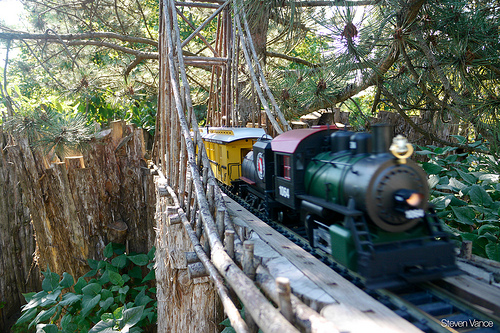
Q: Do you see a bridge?
A: Yes, there is a bridge.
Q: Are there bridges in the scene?
A: Yes, there is a bridge.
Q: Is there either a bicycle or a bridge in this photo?
A: Yes, there is a bridge.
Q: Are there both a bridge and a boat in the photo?
A: No, there is a bridge but no boats.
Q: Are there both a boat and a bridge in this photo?
A: No, there is a bridge but no boats.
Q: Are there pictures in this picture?
A: No, there are no pictures.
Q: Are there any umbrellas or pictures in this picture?
A: No, there are no pictures or umbrellas.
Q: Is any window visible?
A: Yes, there is a window.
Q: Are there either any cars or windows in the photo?
A: Yes, there is a window.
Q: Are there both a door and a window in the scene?
A: No, there is a window but no doors.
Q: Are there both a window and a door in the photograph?
A: No, there is a window but no doors.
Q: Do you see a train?
A: Yes, there is a train.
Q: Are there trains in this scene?
A: Yes, there is a train.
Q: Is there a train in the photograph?
A: Yes, there is a train.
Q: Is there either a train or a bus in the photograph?
A: Yes, there is a train.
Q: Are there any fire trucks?
A: No, there are no fire trucks.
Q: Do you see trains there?
A: Yes, there is a train.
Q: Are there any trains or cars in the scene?
A: Yes, there is a train.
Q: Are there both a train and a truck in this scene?
A: No, there is a train but no trucks.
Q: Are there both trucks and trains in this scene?
A: No, there is a train but no trucks.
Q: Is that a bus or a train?
A: That is a train.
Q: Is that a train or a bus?
A: That is a train.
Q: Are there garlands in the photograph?
A: No, there are no garlands.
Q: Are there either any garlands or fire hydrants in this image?
A: No, there are no garlands or fire hydrants.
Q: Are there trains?
A: Yes, there is a train.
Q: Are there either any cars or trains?
A: Yes, there is a train.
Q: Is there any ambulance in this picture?
A: No, there are no ambulances.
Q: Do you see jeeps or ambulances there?
A: No, there are no ambulances or jeeps.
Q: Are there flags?
A: No, there are no flags.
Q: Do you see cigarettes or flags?
A: No, there are no flags or cigarettes.